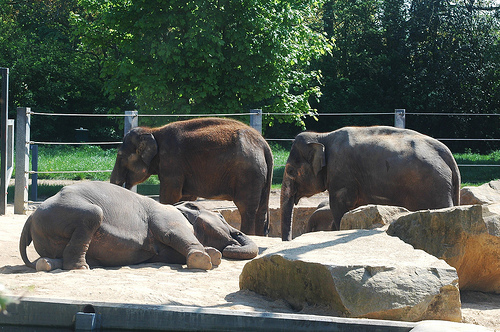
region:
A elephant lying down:
[18, 171, 255, 286]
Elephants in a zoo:
[11, 115, 468, 268]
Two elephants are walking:
[97, 101, 460, 223]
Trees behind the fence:
[21, 10, 471, 102]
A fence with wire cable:
[16, 108, 497, 128]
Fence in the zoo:
[10, 95, 496, 210]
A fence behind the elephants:
[15, 106, 495, 186]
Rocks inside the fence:
[235, 195, 496, 313]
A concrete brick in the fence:
[12, 105, 32, 207]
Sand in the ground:
[15, 259, 239, 294]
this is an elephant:
[280, 131, 460, 202]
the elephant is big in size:
[283, 120, 452, 207]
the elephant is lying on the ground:
[21, 184, 241, 271]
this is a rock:
[249, 219, 429, 314]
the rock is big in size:
[248, 225, 433, 318]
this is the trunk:
[268, 187, 300, 234]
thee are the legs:
[178, 238, 220, 261]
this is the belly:
[101, 196, 148, 247]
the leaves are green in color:
[126, 8, 297, 88]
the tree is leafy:
[110, 11, 280, 73]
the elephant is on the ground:
[26, 172, 253, 273]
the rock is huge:
[236, 219, 459, 315]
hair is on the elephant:
[176, 113, 244, 143]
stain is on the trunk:
[275, 171, 295, 207]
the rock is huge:
[408, 212, 499, 260]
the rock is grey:
[410, 198, 496, 273]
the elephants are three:
[20, 114, 437, 319]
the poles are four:
[12, 101, 415, 201]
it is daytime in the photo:
[2, 50, 482, 325]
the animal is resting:
[32, 180, 259, 287]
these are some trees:
[34, 9, 484, 109]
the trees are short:
[51, 5, 490, 103]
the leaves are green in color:
[81, 0, 132, 65]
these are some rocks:
[253, 202, 498, 294]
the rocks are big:
[237, 203, 498, 314]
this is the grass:
[50, 149, 92, 168]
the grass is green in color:
[45, 144, 90, 167]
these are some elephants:
[28, 117, 475, 298]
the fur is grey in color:
[103, 195, 149, 247]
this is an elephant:
[16, 177, 259, 299]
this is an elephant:
[109, 96, 274, 236]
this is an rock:
[362, 261, 468, 322]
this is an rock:
[237, 222, 462, 327]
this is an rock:
[385, 190, 497, 293]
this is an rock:
[330, 181, 415, 231]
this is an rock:
[456, 175, 496, 205]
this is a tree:
[85, 2, 331, 137]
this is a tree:
[338, 0, 496, 155]